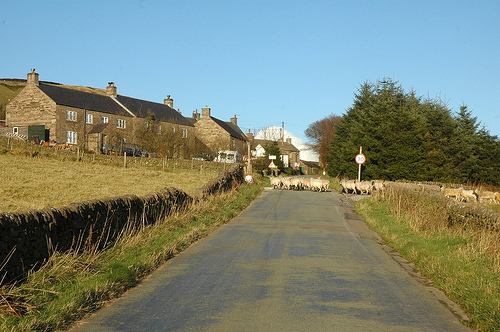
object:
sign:
[354, 154, 366, 165]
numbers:
[361, 157, 365, 161]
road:
[116, 183, 466, 329]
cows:
[308, 177, 331, 193]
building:
[105, 82, 193, 156]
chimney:
[105, 82, 117, 98]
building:
[4, 67, 133, 159]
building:
[160, 94, 197, 161]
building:
[194, 105, 250, 161]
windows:
[67, 110, 77, 121]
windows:
[86, 114, 94, 124]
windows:
[66, 130, 77, 144]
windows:
[117, 118, 126, 129]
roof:
[36, 80, 133, 117]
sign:
[267, 162, 277, 168]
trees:
[330, 78, 434, 177]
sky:
[0, 0, 500, 80]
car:
[107, 141, 145, 157]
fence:
[8, 187, 182, 263]